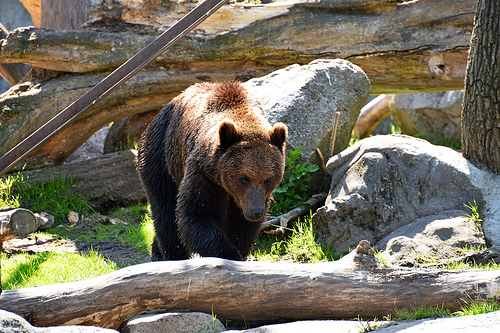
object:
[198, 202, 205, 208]
dirt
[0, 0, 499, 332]
zoo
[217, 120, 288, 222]
head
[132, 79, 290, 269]
bear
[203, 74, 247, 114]
fur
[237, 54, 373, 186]
boulder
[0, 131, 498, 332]
grass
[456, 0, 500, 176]
tree stands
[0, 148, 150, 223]
log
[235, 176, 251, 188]
eye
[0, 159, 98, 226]
green grass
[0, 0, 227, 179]
bar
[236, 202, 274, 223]
mouth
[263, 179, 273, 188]
eyes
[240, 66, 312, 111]
reflection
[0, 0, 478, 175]
logs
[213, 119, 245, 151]
ear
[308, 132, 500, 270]
boulder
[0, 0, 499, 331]
pen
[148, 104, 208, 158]
fur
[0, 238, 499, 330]
log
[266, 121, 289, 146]
ears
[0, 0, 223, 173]
rust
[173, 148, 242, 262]
leg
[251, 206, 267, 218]
nose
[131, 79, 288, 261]
body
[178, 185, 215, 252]
fur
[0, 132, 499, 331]
ground